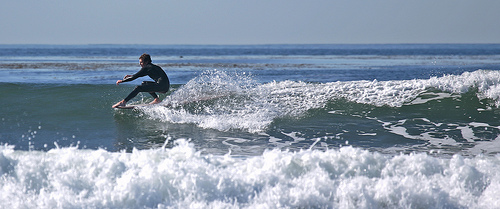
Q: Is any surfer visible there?
A: Yes, there is a surfer.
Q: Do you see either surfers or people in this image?
A: Yes, there is a surfer.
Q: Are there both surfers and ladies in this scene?
A: No, there is a surfer but no ladies.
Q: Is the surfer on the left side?
A: Yes, the surfer is on the left of the image.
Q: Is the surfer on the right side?
A: No, the surfer is on the left of the image.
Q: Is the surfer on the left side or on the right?
A: The surfer is on the left of the image.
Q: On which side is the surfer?
A: The surfer is on the left of the image.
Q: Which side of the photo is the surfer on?
A: The surfer is on the left of the image.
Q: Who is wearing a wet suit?
A: The surfer is wearing a wet suit.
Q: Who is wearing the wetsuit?
A: The surfer is wearing a wet suit.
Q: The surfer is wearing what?
A: The surfer is wearing a wet suit.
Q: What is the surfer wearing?
A: The surfer is wearing a wet suit.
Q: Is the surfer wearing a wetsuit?
A: Yes, the surfer is wearing a wetsuit.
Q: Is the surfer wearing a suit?
A: No, the surfer is wearing a wetsuit.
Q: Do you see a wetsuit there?
A: Yes, there is a wetsuit.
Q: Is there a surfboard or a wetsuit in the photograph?
A: Yes, there is a wetsuit.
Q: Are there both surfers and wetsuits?
A: Yes, there are both a wetsuit and a surfer.